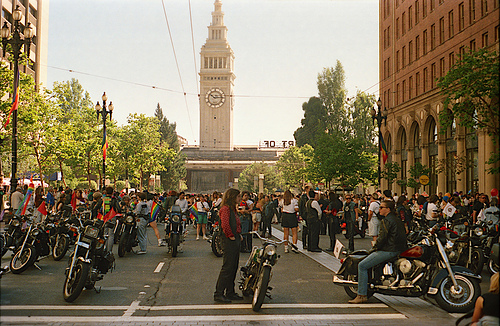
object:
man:
[347, 200, 409, 304]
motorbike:
[330, 226, 482, 314]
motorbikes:
[63, 219, 116, 303]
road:
[16, 220, 318, 319]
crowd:
[34, 185, 414, 275]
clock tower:
[200, 0, 236, 151]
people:
[426, 194, 442, 227]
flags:
[442, 202, 457, 218]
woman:
[213, 204, 244, 304]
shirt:
[219, 203, 243, 237]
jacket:
[371, 211, 410, 254]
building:
[183, 146, 282, 193]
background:
[246, 112, 273, 125]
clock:
[204, 88, 226, 109]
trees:
[150, 102, 185, 192]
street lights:
[100, 91, 110, 101]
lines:
[128, 303, 390, 310]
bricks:
[393, 297, 418, 306]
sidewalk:
[310, 222, 379, 254]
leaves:
[476, 49, 492, 61]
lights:
[22, 22, 35, 39]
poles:
[102, 124, 107, 188]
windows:
[433, 123, 439, 142]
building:
[379, 0, 496, 224]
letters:
[263, 141, 270, 149]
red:
[223, 207, 225, 214]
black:
[224, 273, 231, 278]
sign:
[418, 174, 431, 186]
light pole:
[377, 117, 382, 185]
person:
[196, 194, 210, 240]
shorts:
[195, 211, 208, 224]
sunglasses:
[379, 206, 389, 210]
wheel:
[430, 265, 481, 313]